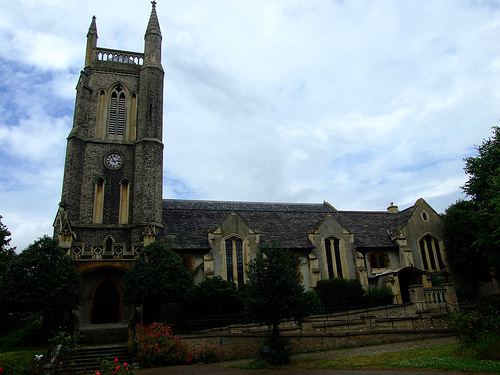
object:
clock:
[103, 152, 123, 170]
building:
[54, 1, 464, 371]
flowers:
[124, 318, 205, 365]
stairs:
[54, 323, 149, 373]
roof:
[160, 196, 416, 247]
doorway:
[86, 273, 124, 325]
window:
[224, 238, 236, 285]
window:
[420, 210, 428, 223]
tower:
[54, 2, 171, 344]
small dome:
[96, 44, 141, 65]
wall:
[65, 220, 138, 259]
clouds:
[1, 0, 485, 211]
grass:
[175, 336, 499, 375]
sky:
[0, 0, 499, 257]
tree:
[124, 237, 193, 334]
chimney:
[386, 201, 400, 214]